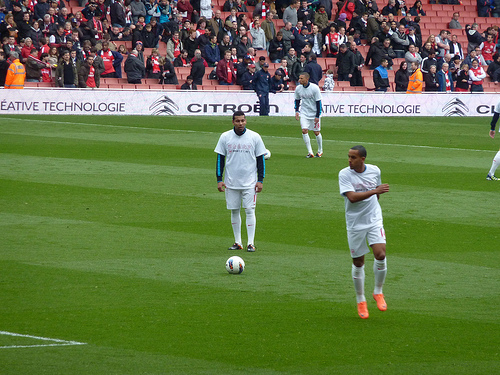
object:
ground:
[1, 114, 497, 373]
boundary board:
[1, 86, 498, 116]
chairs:
[1, 0, 498, 89]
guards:
[2, 49, 26, 89]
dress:
[4, 61, 26, 86]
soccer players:
[212, 73, 397, 318]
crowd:
[0, 0, 499, 91]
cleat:
[356, 297, 370, 321]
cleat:
[369, 283, 389, 308]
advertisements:
[0, 88, 499, 117]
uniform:
[333, 164, 390, 319]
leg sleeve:
[224, 205, 243, 245]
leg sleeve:
[241, 205, 260, 245]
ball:
[224, 254, 247, 273]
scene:
[0, 104, 488, 374]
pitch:
[0, 110, 500, 370]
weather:
[13, 14, 444, 371]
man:
[211, 110, 268, 253]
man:
[291, 72, 324, 157]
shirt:
[209, 127, 270, 189]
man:
[3, 52, 24, 84]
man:
[407, 52, 423, 94]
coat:
[2, 60, 31, 89]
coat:
[407, 71, 428, 94]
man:
[317, 125, 406, 325]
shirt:
[338, 163, 385, 209]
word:
[43, 95, 129, 120]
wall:
[0, 87, 500, 117]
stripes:
[213, 150, 230, 180]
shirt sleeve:
[209, 151, 228, 184]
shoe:
[352, 298, 371, 320]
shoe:
[368, 288, 393, 310]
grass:
[1, 113, 499, 372]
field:
[0, 115, 499, 373]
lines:
[3, 324, 90, 360]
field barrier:
[0, 89, 497, 120]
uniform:
[214, 131, 269, 241]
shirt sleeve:
[254, 150, 269, 185]